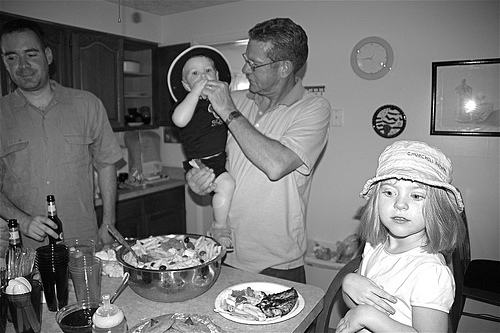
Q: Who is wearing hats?
A: Two kids.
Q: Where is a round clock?
A: On the wall.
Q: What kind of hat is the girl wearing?
A: A bucket hat.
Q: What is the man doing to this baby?
A: Feeding.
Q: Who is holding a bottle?
A: A man with short dark hair.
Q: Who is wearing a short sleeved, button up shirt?
A: The man holding the bottle.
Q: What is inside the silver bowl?
A: A fruit salad.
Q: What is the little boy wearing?
A: A black hat.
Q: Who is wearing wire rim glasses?
A: The man holding the baby.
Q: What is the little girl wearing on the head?
A: A white hat.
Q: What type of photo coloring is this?
A: Black and white.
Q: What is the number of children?
A: Two.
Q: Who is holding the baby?
A: The man with glasses.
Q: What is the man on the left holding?
A: A bottle of beer.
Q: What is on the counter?
A: Food and drinks.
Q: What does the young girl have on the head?
A: A hat.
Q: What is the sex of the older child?
A: A female.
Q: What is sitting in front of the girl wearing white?
A: A plate of food.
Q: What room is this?
A: Kitchen.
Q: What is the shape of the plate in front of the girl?
A: Round.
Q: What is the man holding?
A: A baby.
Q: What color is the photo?
A: Black and white.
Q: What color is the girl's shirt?
A: White.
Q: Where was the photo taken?
A: In a kitchen.